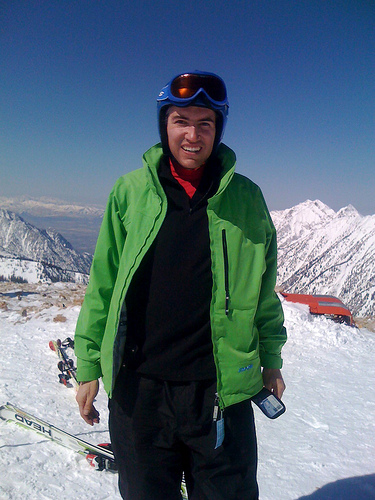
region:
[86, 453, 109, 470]
bindings on the ski.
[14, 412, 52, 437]
writing on the ski.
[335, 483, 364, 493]
shadow in the snow.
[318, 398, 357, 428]
snow on the ground.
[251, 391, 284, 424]
phone in man's hand.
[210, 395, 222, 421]
zipper on the jacket.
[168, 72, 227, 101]
goggles on man's head.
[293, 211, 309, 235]
snow on the mountain.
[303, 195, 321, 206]
peak of the mountain.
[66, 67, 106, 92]
clear blue sky above mountains.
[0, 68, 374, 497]
Man standing in show smiling.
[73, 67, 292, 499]
Man wearing black pants.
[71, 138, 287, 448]
Green jacket with black zipper.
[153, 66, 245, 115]
Blue glasses with red lenses.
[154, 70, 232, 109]
White letter s on red glasses with red lenses.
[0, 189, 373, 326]
Tall snow capped mountains.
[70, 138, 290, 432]
Blue tag hanging from green jacket.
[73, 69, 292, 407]
Blue letters on left hand pocket of green jacket.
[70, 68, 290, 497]
Man wearing red turtleneck sweater under ski clothes.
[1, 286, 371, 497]
Edge of orange and grey vehicle parked behind snow.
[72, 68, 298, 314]
Man wearing green jacket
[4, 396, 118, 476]
Pair of snow skis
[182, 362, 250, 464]
A tag hanging on the front of the mans jacket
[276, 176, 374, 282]
Snow covered mountains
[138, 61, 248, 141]
Blue ski goggles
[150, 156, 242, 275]
Black and orange shirt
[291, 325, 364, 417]
Snow on the ground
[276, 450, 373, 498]
Shadow on the snow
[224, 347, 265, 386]
Blue design on green jacket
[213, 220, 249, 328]
Black zipper on green jacket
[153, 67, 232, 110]
Blue goggles with orange lenses.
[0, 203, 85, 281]
Mountains in the distance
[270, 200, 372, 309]
mountains in the distance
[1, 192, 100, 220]
faraway mountian range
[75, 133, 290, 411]
Green jacket wiith black zippers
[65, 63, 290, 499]
Man wearing a green jacket.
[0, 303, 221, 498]
Two pairs of skis on the snow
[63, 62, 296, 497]
man wearing black shirt under green parka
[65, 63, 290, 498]
man wearing goggles on his head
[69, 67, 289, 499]
man wearing red shirt underneath black shirt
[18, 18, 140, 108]
The sky is clear and blue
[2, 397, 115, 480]
The snow skis on the ground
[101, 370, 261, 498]
The man is wearing pants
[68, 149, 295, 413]
The man is wearing a green jacket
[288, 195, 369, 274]
The mountains are covered in ice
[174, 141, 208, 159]
The man is smiling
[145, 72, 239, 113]
The man has on snow goggles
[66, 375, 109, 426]
The hand of the man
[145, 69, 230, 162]
The man is wearing a helmet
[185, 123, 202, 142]
The nose of the man